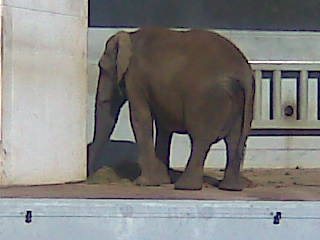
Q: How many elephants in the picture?
A: One.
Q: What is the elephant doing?
A: Standing.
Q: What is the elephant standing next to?
A: A wall.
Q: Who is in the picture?
A: An elephant.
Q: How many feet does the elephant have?
A: Four.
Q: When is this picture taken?
A: Daytime.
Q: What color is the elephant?
A: Gray.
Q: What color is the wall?
A: White.